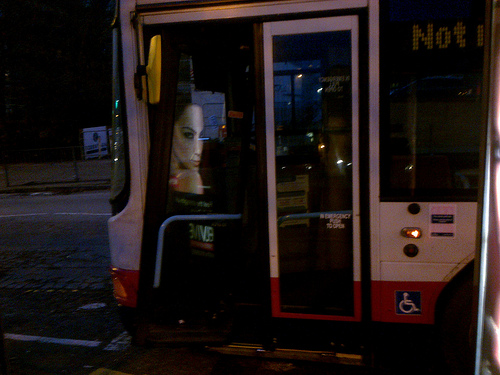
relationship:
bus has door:
[99, 14, 461, 339] [259, 17, 365, 311]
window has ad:
[164, 49, 238, 244] [174, 96, 215, 193]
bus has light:
[99, 14, 461, 339] [387, 224, 425, 239]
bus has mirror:
[99, 14, 461, 339] [125, 38, 170, 93]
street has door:
[35, 208, 109, 305] [259, 14, 368, 325]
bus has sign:
[99, 14, 461, 339] [383, 277, 428, 326]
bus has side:
[99, 14, 461, 339] [241, 4, 499, 287]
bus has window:
[99, 14, 461, 339] [164, 49, 238, 244]